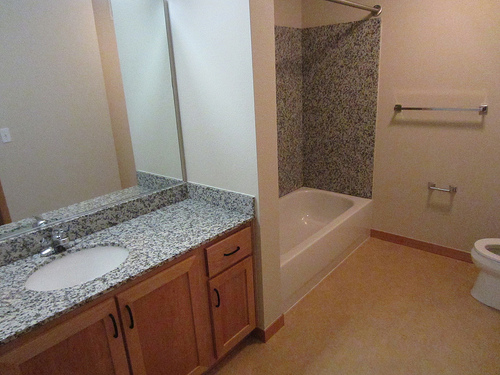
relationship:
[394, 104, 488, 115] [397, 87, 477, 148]
handle hanging towel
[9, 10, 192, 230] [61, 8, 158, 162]
mirror reflects wall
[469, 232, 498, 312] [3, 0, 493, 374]
toilet in bathroom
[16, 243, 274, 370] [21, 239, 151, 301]
counters under sink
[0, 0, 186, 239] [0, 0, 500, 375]
mirror on bathroom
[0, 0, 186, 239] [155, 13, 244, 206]
mirror on wall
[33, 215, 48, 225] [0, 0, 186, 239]
reflection on mirror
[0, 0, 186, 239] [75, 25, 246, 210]
mirror front handwash